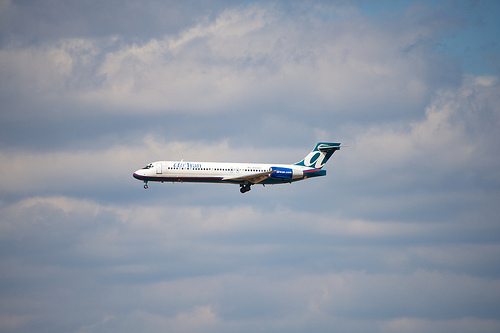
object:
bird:
[131, 141, 342, 193]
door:
[155, 162, 163, 175]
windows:
[141, 162, 154, 170]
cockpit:
[133, 156, 160, 186]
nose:
[131, 169, 148, 180]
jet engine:
[269, 167, 304, 180]